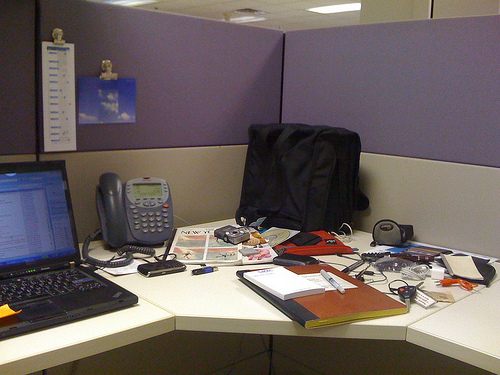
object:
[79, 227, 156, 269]
cord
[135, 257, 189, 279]
telephone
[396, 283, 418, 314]
keys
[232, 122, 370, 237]
black bag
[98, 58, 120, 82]
clip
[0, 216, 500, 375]
desk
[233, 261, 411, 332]
book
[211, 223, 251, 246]
camera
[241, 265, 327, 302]
notepad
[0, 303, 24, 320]
orange sticker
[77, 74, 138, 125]
paper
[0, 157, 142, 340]
laptop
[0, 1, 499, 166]
wall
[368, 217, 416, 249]
item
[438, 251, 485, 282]
item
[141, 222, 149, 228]
key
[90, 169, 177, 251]
phone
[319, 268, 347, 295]
pen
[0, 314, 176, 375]
side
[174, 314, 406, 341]
side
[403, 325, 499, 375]
side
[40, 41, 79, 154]
paper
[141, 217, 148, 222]
key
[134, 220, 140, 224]
key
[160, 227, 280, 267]
magazine